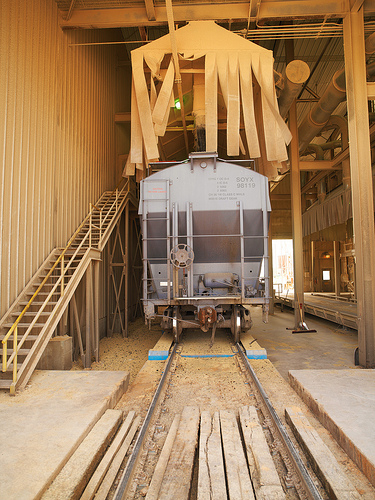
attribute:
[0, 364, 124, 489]
ground — dusty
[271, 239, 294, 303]
door — open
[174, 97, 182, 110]
light — green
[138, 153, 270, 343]
train car — grey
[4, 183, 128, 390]
staircase — tall, tan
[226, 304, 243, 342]
wheel — silver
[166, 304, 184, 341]
wheel — silver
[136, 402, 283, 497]
planks — wooden, light brown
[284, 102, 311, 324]
column — tall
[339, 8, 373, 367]
support — metal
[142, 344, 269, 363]
spray — blue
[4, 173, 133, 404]
stairs — metal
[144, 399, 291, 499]
planks — wood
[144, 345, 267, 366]
paint — blue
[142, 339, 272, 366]
planks — wooden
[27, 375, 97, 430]
platform — concrete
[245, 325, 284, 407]
track — steel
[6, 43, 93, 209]
wall — metal corrugated, yellow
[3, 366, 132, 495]
platform — concrete 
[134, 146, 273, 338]
carrier — big, gray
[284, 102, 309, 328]
beam — large, steel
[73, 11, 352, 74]
ceiling — metal